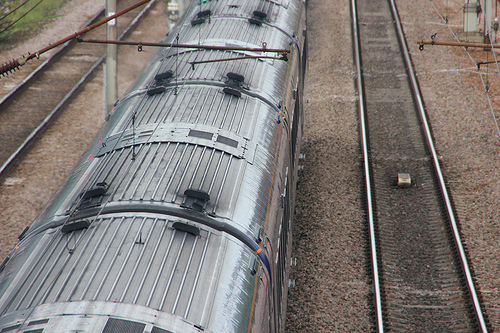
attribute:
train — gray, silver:
[45, 21, 260, 322]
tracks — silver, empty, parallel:
[358, 61, 428, 159]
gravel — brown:
[305, 11, 361, 331]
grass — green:
[14, 10, 39, 26]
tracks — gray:
[21, 68, 73, 111]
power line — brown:
[35, 43, 69, 56]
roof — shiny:
[85, 236, 189, 295]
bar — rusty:
[113, 38, 215, 48]